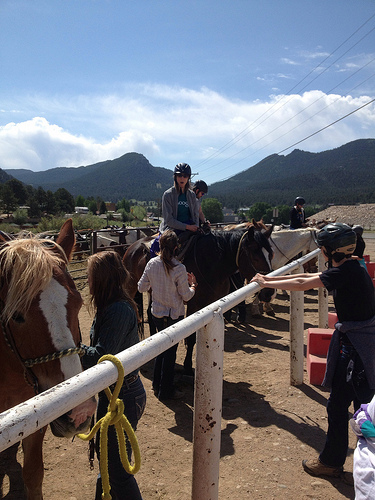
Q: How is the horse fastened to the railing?
A: With a rope.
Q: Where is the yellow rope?
A: On the railing.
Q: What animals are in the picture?
A: Horses.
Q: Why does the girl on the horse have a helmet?
A: For protection.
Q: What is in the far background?
A: Mountains.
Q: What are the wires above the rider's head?
A: Power lines.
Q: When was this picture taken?
A: During the day.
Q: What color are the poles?
A: White.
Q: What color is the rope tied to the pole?
A: Yellow.